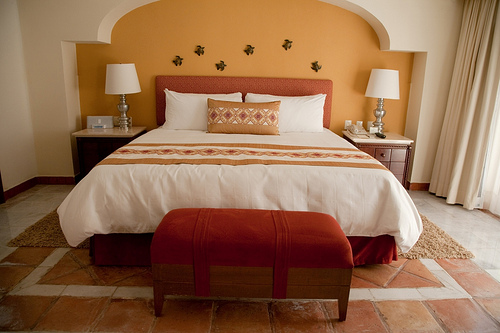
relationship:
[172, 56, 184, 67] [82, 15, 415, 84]
turtle on background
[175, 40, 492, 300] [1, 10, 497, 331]
sunlight in room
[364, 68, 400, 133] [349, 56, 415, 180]
lamp on left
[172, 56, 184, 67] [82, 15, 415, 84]
turtle on wall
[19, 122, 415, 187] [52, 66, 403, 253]
two nightstands by bed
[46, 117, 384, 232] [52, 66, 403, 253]
bedspread on bed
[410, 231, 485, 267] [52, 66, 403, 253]
carpet on bed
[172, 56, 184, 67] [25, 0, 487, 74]
turtle on wall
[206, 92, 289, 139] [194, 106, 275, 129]
pillow with design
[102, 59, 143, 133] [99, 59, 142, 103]
lamp with shade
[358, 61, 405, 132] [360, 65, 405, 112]
lamp with shade